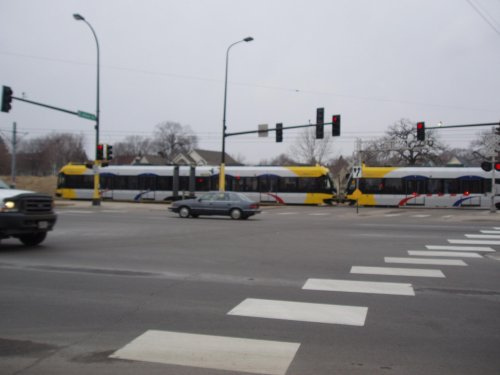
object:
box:
[226, 298, 368, 327]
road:
[0, 199, 499, 374]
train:
[55, 160, 500, 209]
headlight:
[5, 201, 15, 208]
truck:
[1, 183, 57, 249]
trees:
[112, 120, 199, 164]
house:
[109, 147, 245, 165]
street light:
[243, 36, 254, 42]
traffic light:
[417, 121, 425, 141]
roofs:
[101, 147, 235, 163]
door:
[406, 175, 425, 206]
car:
[167, 191, 261, 220]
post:
[79, 13, 100, 203]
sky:
[0, 0, 500, 164]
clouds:
[268, 11, 464, 98]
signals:
[258, 108, 341, 142]